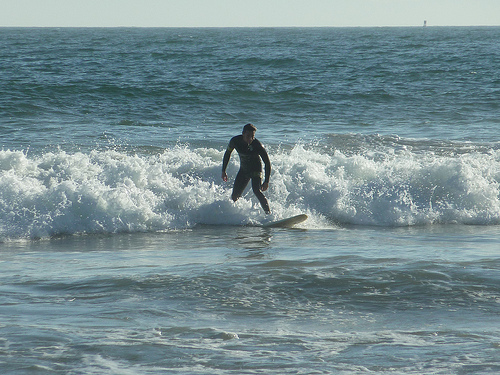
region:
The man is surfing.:
[206, 105, 319, 242]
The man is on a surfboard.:
[191, 105, 314, 237]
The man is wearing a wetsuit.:
[206, 113, 314, 236]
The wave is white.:
[1, 129, 499, 256]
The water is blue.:
[2, 26, 499, 138]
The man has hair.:
[213, 110, 310, 240]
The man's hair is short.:
[221, 110, 280, 219]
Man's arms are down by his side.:
[213, 118, 279, 233]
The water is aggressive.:
[2, 27, 498, 373]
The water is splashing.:
[1, 25, 497, 372]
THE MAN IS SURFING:
[258, 209, 310, 231]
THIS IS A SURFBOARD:
[257, 208, 315, 241]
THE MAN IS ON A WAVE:
[0, 123, 499, 227]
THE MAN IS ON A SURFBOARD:
[258, 208, 308, 235]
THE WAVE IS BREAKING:
[0, 127, 498, 251]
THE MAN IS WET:
[206, 115, 286, 225]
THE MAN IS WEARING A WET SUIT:
[216, 130, 276, 224]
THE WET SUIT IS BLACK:
[217, 130, 275, 217]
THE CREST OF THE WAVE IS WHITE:
[0, 129, 499, 246]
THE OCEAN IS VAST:
[0, 23, 498, 367]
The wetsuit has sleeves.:
[209, 115, 311, 236]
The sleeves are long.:
[212, 115, 278, 197]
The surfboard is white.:
[243, 203, 315, 236]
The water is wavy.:
[4, 26, 497, 371]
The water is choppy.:
[5, 37, 498, 363]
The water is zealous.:
[3, 32, 499, 374]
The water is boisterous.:
[4, 32, 496, 371]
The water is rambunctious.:
[3, 31, 498, 371]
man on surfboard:
[213, 120, 306, 229]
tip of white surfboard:
[281, 212, 306, 227]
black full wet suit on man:
[213, 137, 265, 214]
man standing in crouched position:
[220, 126, 274, 213]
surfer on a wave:
[211, 127, 305, 237]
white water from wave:
[27, 155, 144, 227]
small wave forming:
[53, 80, 183, 116]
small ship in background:
[416, 18, 437, 32]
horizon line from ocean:
[80, 20, 385, 35]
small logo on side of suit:
[254, 143, 264, 152]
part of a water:
[313, 260, 353, 310]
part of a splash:
[418, 161, 468, 219]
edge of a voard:
[287, 195, 337, 227]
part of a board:
[272, 175, 314, 254]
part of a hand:
[258, 170, 274, 188]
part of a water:
[291, 258, 330, 295]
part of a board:
[248, 184, 351, 331]